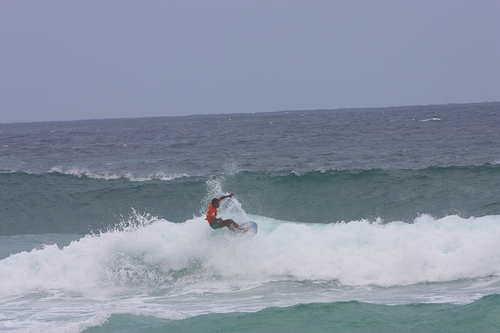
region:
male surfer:
[197, 187, 232, 231]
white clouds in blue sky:
[397, 42, 456, 74]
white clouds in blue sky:
[28, 12, 54, 50]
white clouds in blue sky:
[221, 17, 291, 65]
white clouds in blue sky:
[171, 20, 237, 75]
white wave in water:
[34, 248, 64, 273]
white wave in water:
[89, 237, 106, 256]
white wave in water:
[120, 235, 160, 275]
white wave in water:
[162, 238, 193, 270]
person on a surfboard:
[203, 191, 260, 240]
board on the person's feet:
[228, 217, 265, 242]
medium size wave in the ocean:
[4, 212, 494, 332]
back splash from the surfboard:
[201, 178, 247, 225]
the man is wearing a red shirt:
[207, 192, 217, 221]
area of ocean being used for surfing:
[0, 107, 499, 331]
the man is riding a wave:
[198, 193, 260, 243]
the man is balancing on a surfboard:
[200, 175, 260, 240]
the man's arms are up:
[201, 189, 239, 221]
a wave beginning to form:
[3, 157, 490, 186]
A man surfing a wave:
[186, 183, 268, 253]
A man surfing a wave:
[194, 185, 264, 251]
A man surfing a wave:
[188, 183, 261, 249]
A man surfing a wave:
[184, 186, 264, 251]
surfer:
[193, 182, 248, 243]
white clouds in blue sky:
[377, 21, 451, 72]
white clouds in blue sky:
[57, 25, 142, 80]